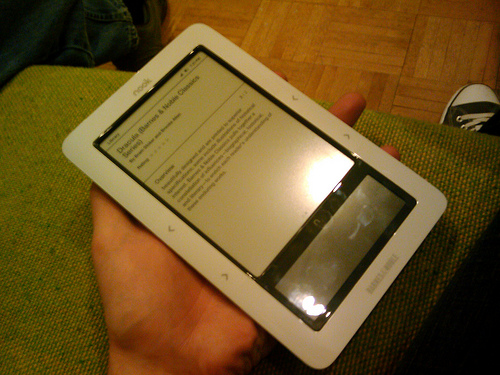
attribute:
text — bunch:
[106, 56, 279, 216]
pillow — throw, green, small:
[9, 179, 63, 293]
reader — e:
[90, 60, 458, 348]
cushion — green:
[5, 55, 499, 374]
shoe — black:
[437, 79, 499, 131]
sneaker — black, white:
[438, 84, 498, 131]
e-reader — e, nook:
[63, 21, 448, 371]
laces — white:
[456, 110, 497, 130]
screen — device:
[115, 56, 389, 309]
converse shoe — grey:
[436, 81, 498, 133]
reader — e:
[56, 20, 448, 367]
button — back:
[208, 261, 241, 292]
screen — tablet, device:
[93, 43, 418, 331]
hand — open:
[87, 73, 399, 372]